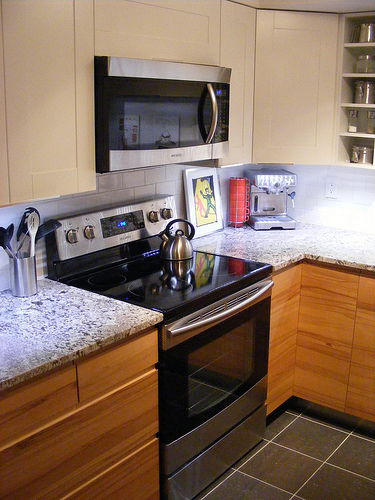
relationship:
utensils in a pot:
[2, 207, 62, 258] [5, 251, 37, 298]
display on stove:
[98, 211, 145, 238] [46, 194, 273, 499]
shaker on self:
[366, 110, 374, 136] [340, 131, 374, 139]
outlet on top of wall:
[325, 180, 337, 199] [1, 163, 373, 291]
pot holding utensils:
[5, 251, 37, 298] [2, 207, 62, 258]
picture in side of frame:
[183, 168, 225, 239] [181, 166, 225, 235]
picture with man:
[183, 168, 225, 239] [195, 179, 216, 224]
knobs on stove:
[67, 205, 173, 244] [46, 194, 273, 499]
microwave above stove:
[93, 55, 233, 172] [46, 194, 273, 499]